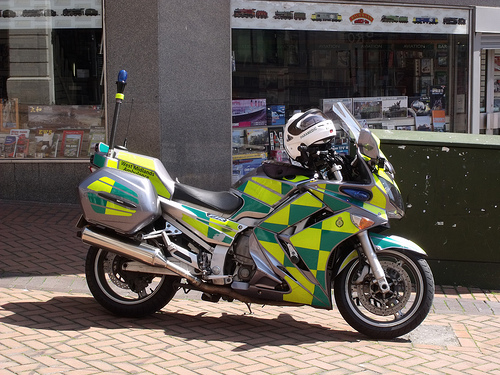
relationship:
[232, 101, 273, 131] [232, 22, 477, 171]
magazine in window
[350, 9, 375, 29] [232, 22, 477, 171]
sign above window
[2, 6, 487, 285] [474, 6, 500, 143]
building has door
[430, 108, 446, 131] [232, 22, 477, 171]
box on window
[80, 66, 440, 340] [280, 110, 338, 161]
motorbike has helmet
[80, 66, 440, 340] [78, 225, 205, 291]
motorbike has exhaust pipe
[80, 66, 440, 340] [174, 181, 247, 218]
motorbike has seat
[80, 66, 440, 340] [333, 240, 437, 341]
motorbike has wheel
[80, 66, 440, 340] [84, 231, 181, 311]
motorbike has wheel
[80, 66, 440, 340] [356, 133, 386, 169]
motorbike has mirror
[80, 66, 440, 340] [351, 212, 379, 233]
motorbike has light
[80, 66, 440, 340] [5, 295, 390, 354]
motorbike has shadow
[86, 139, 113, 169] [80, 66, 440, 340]
light on motorbike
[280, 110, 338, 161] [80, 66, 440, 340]
helmet on motorbike